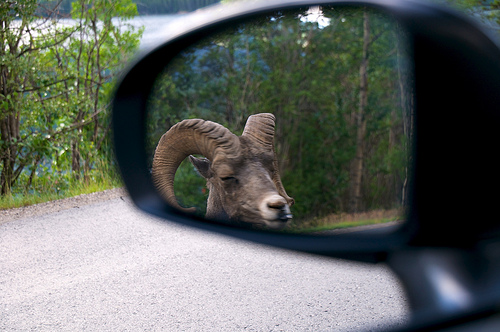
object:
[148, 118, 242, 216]
horn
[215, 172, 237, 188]
eye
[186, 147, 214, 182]
ear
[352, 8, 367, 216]
tree trunk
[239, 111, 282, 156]
horns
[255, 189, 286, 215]
snout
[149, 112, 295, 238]
head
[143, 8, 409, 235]
mirror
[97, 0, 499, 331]
car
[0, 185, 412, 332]
roadway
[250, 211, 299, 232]
mouth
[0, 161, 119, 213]
grass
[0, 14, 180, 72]
water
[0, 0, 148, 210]
trees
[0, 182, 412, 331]
road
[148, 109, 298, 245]
goat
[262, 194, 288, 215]
nose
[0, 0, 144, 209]
bushes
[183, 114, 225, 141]
ridges